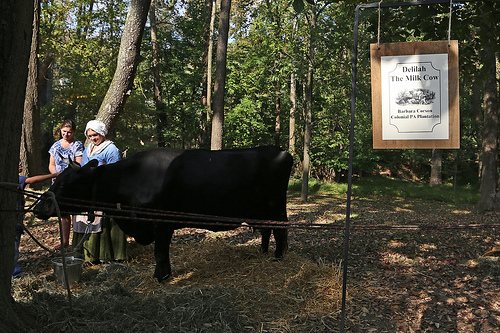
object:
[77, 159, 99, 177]
ear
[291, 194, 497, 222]
ground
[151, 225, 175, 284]
leg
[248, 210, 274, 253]
leg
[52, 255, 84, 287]
metal bucket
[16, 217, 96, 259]
rope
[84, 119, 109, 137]
bonnet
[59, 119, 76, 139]
head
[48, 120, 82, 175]
person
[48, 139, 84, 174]
shirt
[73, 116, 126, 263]
woman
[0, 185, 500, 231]
rope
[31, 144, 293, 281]
cow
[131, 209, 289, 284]
four legs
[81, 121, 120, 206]
person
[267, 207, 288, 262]
leg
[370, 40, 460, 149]
sign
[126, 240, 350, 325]
hay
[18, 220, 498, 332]
ground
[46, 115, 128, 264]
two people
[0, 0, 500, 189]
woods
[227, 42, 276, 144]
leaves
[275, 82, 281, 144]
tree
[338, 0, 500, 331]
bar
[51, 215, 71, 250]
legs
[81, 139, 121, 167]
shirt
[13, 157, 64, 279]
people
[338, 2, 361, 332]
pole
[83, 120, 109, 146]
head